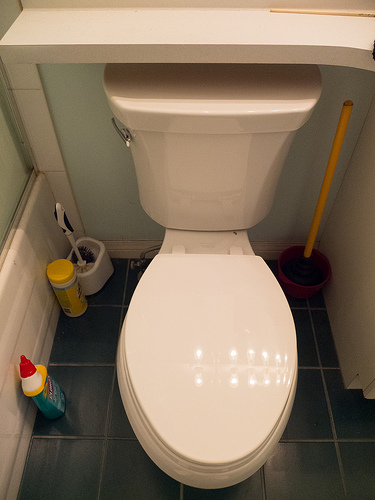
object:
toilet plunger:
[280, 99, 360, 289]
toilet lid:
[118, 252, 297, 466]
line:
[318, 365, 344, 440]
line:
[96, 433, 113, 497]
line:
[49, 360, 115, 369]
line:
[277, 437, 334, 443]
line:
[298, 365, 341, 369]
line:
[288, 304, 327, 309]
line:
[333, 439, 353, 497]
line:
[259, 464, 268, 498]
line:
[178, 485, 184, 498]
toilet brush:
[51, 200, 97, 273]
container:
[66, 235, 116, 297]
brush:
[52, 200, 95, 271]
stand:
[64, 236, 114, 296]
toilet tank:
[100, 61, 327, 230]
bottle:
[15, 351, 69, 419]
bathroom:
[1, 1, 373, 499]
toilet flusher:
[109, 114, 132, 152]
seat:
[120, 240, 305, 459]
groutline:
[46, 358, 116, 370]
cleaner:
[43, 256, 88, 318]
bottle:
[46, 258, 87, 317]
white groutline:
[94, 261, 135, 481]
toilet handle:
[110, 116, 131, 145]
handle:
[301, 98, 356, 259]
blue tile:
[7, 228, 372, 498]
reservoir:
[102, 63, 324, 230]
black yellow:
[300, 96, 355, 261]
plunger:
[282, 247, 329, 285]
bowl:
[271, 249, 332, 296]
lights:
[174, 345, 303, 395]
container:
[42, 253, 91, 319]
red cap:
[15, 352, 38, 379]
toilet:
[102, 63, 326, 487]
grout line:
[28, 432, 135, 441]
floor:
[17, 257, 374, 498]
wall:
[35, 63, 373, 260]